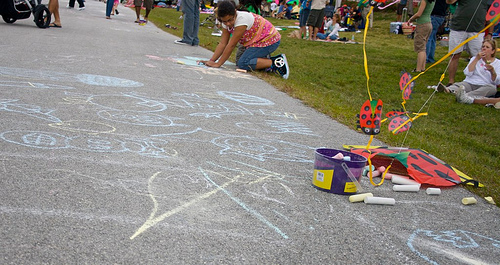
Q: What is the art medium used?
A: Chalk.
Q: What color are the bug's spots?
A: Black.